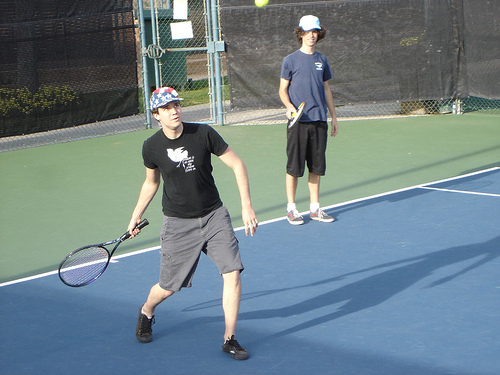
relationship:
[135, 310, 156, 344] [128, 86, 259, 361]
shoe on boy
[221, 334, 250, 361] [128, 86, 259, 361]
sneakers of boy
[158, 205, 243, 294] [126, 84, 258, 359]
shorts of man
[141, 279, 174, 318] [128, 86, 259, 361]
bare leg of boy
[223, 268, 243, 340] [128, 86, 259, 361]
leg of boy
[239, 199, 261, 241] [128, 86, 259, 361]
hand of boy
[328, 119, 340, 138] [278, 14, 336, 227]
hand of boy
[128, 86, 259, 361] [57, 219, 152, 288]
boy with black racket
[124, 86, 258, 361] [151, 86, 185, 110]
boy in hat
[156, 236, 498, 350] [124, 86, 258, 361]
shadow of boy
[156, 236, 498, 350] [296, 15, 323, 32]
shadow on baseball cap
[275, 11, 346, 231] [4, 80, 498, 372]
boy on tennis court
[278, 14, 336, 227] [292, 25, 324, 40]
boy with hair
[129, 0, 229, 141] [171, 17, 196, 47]
fence with paper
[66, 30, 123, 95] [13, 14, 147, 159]
fence with cover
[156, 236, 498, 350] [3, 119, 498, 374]
shadow on court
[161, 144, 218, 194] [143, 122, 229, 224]
print on tshirt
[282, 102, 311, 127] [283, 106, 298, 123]
racquet in hand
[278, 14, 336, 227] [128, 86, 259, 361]
boy observing boy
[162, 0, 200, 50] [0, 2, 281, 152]
signs posted on court gate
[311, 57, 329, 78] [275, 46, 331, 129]
print on shirt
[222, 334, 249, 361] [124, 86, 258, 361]
shoe on boy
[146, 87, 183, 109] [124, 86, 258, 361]
cap on boy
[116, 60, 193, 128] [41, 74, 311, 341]
hat on boy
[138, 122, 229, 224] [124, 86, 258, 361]
tshirt on boy